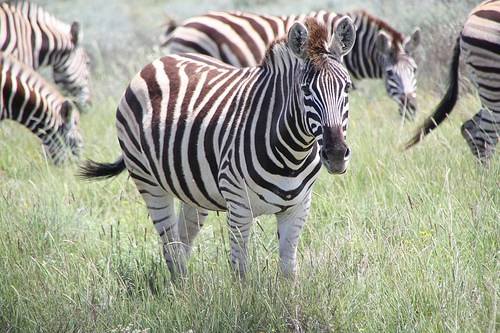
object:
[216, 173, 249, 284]
leg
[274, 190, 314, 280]
leg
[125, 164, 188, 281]
leg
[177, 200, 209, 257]
leg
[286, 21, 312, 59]
ear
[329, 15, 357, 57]
ear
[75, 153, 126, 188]
tail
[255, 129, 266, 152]
black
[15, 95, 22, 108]
black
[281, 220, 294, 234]
white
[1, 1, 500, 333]
grass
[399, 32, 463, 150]
tail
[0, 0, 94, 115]
zebras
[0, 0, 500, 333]
field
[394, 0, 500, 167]
zebra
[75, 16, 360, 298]
zebra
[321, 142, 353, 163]
nose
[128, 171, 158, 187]
stripes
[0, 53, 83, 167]
zebra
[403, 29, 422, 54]
ear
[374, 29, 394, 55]
ear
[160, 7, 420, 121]
zebra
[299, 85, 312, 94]
eye